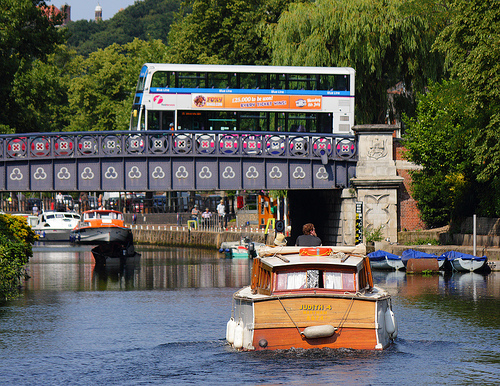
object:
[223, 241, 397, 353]
boat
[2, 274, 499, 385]
water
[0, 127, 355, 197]
bridge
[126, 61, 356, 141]
bus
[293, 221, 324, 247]
man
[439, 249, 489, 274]
boats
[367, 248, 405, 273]
blue tarps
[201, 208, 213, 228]
people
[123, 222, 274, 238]
side walk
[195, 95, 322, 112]
ad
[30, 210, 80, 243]
boat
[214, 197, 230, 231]
person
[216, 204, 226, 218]
white shirt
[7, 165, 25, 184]
decorations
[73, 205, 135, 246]
boat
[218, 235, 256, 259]
boats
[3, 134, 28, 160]
circles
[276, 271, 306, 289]
windows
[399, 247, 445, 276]
boat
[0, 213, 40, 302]
bush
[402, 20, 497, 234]
tree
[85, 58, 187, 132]
trees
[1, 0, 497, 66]
background